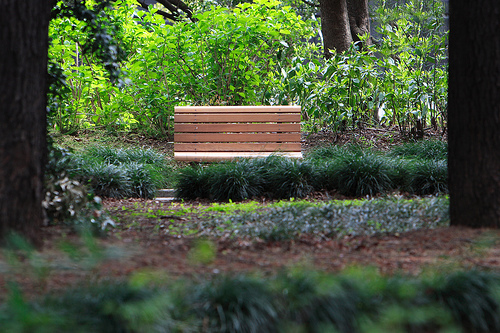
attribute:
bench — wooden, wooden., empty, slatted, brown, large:
[174, 102, 308, 161]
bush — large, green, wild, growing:
[120, 0, 318, 104]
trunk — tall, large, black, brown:
[7, 0, 66, 248]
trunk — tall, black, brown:
[445, 2, 499, 227]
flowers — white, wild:
[155, 202, 450, 238]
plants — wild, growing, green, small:
[51, 1, 445, 235]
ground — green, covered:
[9, 127, 496, 327]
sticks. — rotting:
[326, 116, 450, 150]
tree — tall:
[7, 2, 192, 238]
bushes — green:
[71, 163, 449, 211]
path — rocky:
[155, 166, 184, 244]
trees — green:
[56, 0, 382, 60]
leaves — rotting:
[211, 217, 487, 278]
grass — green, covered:
[105, 196, 476, 240]